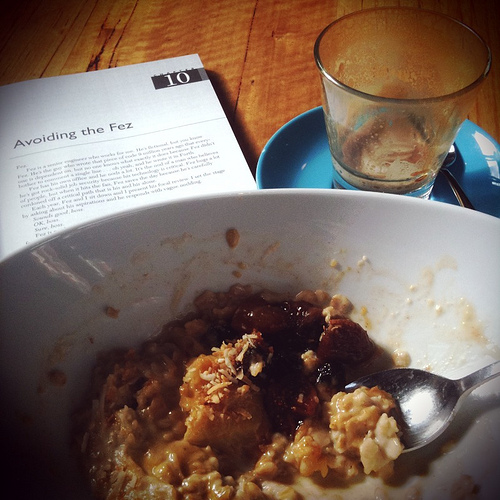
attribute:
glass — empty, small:
[305, 3, 492, 177]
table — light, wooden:
[3, 3, 498, 221]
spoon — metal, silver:
[387, 348, 497, 468]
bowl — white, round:
[8, 184, 496, 499]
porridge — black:
[77, 287, 411, 499]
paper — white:
[1, 54, 255, 262]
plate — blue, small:
[252, 100, 500, 216]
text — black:
[16, 128, 220, 238]